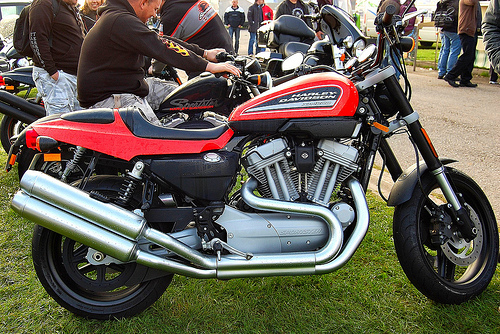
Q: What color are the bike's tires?
A: Black.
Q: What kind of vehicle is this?
A: Motorcycle.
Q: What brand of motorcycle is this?
A: Harley Davidson.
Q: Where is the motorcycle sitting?
A: In the grass.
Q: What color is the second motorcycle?
A: It is black.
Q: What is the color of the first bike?
A: Orange and black.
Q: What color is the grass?
A: Green.